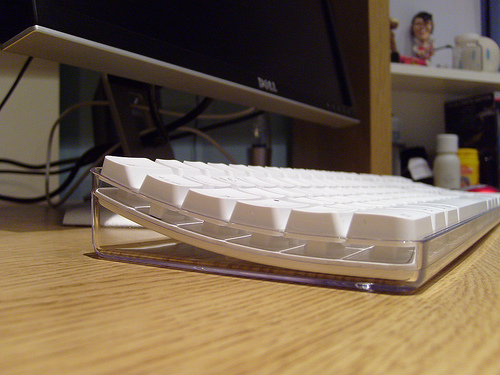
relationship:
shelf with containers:
[393, 38, 477, 128] [432, 134, 462, 190]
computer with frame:
[9, 2, 384, 124] [137, 54, 330, 121]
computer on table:
[0, 0, 361, 227] [2, 197, 497, 374]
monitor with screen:
[9, 15, 491, 177] [274, 54, 342, 96]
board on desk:
[113, 160, 498, 243] [77, 285, 369, 370]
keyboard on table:
[90, 154, 486, 285] [2, 197, 497, 374]